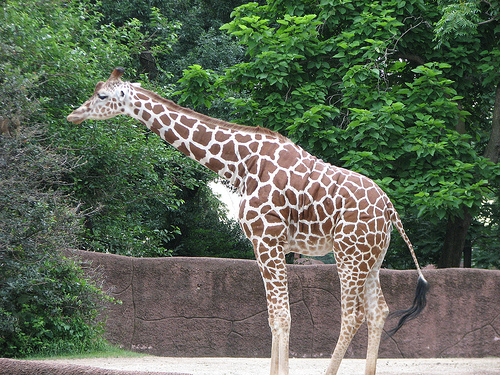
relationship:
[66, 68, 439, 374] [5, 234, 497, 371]
giraffe in enclosure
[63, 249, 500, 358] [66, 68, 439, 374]
concrete wall behind giraffe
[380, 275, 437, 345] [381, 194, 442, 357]
hair hanging from tail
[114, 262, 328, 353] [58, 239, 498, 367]
cracks in wall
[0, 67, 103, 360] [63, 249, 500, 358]
bush by concrete wall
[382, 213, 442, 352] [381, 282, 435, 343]
tail has hair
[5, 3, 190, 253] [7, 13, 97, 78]
tree has foilage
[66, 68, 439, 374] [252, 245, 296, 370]
giraffe has leg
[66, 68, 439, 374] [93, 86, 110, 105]
giraffe has eye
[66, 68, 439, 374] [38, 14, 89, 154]
giraffe grazing on leaves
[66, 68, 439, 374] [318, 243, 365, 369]
giraffe has leg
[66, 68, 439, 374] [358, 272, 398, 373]
giraffe has leg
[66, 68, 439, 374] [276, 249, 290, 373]
giraffe has leg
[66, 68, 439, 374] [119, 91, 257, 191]
giraffe has neck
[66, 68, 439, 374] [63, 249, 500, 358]
giraffe in concrete wall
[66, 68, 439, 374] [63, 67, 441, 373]
giraffe has tail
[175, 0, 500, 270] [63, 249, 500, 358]
tree around concrete wall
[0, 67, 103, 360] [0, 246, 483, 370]
bush near giraffe habitat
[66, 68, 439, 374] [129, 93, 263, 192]
giraffe has neck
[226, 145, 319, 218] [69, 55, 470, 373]
spots on giraffe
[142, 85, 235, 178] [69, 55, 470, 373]
neck on giraffe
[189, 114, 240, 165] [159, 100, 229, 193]
spots on neck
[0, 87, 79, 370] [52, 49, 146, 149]
bush by head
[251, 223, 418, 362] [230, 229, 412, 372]
legs on giraffe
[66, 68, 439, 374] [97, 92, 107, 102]
giraffe has eye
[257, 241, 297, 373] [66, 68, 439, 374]
leg has giraffe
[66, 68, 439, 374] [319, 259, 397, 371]
giraffe has legs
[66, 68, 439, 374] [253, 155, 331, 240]
giraffe has midsection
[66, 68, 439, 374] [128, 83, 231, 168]
giraffe has neck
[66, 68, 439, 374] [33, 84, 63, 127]
giraffe eats tree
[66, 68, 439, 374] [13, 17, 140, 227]
giraffe eats tree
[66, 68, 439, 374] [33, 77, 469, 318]
giraffe eats leaves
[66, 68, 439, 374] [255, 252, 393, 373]
giraffe eats legs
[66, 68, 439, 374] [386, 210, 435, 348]
giraffe has tail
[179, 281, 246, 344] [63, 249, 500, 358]
crack on concrete wall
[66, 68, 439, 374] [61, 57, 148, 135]
giraffe has head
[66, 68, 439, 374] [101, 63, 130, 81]
giraffe has horns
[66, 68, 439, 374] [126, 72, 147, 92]
giraffe has ear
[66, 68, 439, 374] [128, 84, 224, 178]
giraffe has neck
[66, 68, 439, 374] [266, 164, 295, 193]
giraffe has spots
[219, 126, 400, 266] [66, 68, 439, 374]
body has giraffe